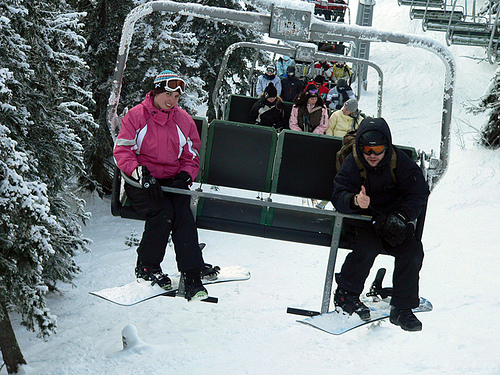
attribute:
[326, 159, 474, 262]
coat — black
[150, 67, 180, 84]
hat — colorful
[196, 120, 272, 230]
empty seat — black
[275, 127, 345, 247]
empty seat — black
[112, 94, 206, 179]
shirt — pink , white s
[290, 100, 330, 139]
pink coat — brown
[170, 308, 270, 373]
surface — snowy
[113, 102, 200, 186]
jacket — pink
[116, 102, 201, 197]
jacket — pink, white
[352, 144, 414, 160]
goggles — pictured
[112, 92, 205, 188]
coat — pink and white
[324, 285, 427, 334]
shoes — black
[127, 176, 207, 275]
pants — black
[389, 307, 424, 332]
boot — snow boot, black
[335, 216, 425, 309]
pants — black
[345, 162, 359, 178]
black jacket — pictured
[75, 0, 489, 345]
lift — ski lift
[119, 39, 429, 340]
people — two people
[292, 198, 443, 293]
pants — black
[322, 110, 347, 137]
jacket — yellow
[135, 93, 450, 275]
seats — empty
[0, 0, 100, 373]
tree — pine tree, green, snow covered